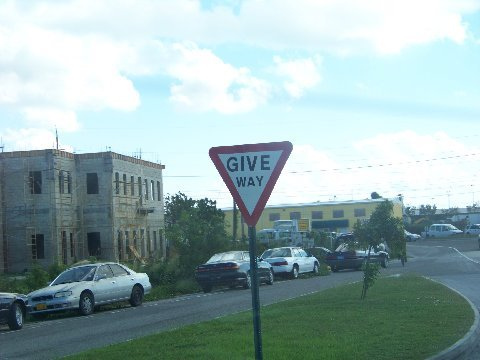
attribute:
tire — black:
[77, 290, 96, 317]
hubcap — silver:
[83, 297, 93, 312]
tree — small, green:
[348, 198, 408, 300]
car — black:
[194, 251, 276, 292]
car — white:
[260, 245, 322, 278]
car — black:
[327, 238, 389, 272]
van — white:
[428, 221, 460, 236]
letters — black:
[234, 175, 265, 188]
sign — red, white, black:
[207, 141, 293, 225]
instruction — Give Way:
[225, 155, 272, 188]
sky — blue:
[378, 69, 435, 114]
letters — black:
[217, 160, 274, 179]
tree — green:
[352, 205, 416, 313]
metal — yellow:
[125, 189, 159, 257]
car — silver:
[198, 231, 276, 293]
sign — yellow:
[179, 132, 308, 207]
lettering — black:
[224, 142, 272, 201]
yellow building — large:
[204, 195, 410, 254]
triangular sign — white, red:
[210, 139, 290, 227]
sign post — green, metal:
[240, 221, 272, 357]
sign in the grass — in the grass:
[204, 138, 343, 358]